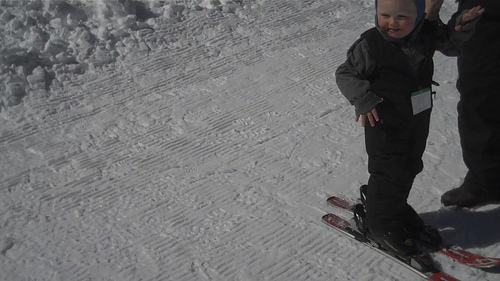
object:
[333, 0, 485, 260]
child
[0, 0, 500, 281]
snow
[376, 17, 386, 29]
babycheek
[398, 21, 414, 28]
babycheek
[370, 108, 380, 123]
finger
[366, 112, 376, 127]
finger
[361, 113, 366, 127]
finger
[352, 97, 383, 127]
hand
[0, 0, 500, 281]
ground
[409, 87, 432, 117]
tag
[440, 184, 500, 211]
shoe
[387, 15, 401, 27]
nose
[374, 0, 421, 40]
head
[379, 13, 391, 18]
eye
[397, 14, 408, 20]
eye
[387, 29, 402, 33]
lip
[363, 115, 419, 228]
leg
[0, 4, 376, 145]
ski track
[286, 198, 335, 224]
ski track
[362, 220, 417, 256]
foot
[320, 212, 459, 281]
ski